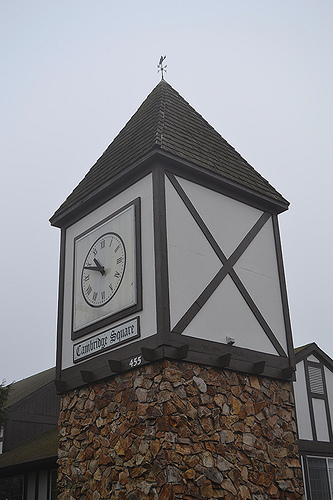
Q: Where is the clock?
A: On the tower.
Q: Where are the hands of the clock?
A: On the face of the clock.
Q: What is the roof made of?
A: Shingles.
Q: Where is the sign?
A: Under the clock.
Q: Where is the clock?
A: On tower.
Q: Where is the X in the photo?
A: On tower.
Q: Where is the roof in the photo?
A: On tower.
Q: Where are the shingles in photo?
A: On tower.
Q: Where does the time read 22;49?
A: The clock.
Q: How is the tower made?
A: Of stone.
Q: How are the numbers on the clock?
A: Roman numerals.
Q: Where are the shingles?
A: The roof.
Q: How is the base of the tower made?
A: Of rock.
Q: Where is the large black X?
A: Clock tower.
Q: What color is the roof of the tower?
A: Black.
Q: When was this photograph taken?
A: 10:50.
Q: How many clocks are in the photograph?
A: One.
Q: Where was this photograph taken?
A: Cambridge Square.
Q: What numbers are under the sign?
A: 455.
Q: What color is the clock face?
A: White.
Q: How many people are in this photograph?
A: Zero.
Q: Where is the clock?
A: On the tower.